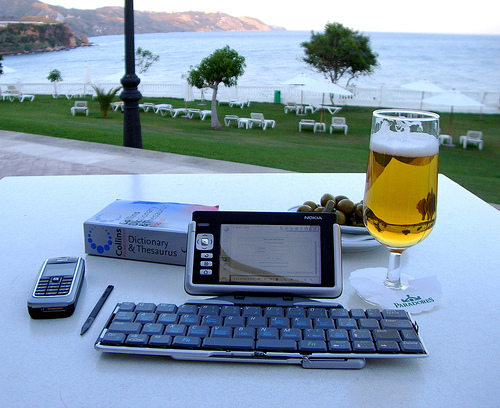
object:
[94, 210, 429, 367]
computer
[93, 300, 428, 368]
keyboard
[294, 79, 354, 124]
umbrella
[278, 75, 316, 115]
umbrella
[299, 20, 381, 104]
tree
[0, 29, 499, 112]
water